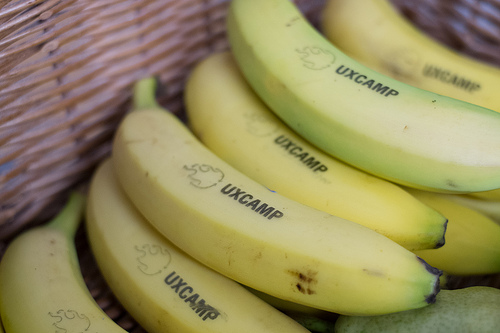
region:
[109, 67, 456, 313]
yellow banana with black lettering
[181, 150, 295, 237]
black lettering spelling uxcamp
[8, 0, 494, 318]
yellow bananas in brown basket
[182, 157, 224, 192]
black flame design on banana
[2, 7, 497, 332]
outdoor foreign market scene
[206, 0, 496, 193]
unripe slightly green banana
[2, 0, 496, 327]
brown wicker basket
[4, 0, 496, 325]
seven bananas visible in basket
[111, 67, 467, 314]
yellow banana with green stem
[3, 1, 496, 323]
yellow bananas with black stamps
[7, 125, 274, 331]
Three yellow bananas.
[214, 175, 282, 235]
Black letters that say uxcamp.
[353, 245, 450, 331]
Bottom of a banana peel.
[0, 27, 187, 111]
Brown woven side of a basket.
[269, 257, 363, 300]
Slight bruising of a banana skin.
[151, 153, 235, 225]
Flame symbol on a banana.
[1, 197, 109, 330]
Yellow banana in basket.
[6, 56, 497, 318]
Seven bananas in a basket.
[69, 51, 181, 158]
Top of a banana.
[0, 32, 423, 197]
Bananas in a basket.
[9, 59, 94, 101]
pink grooves in basket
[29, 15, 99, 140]
black lines in pink basket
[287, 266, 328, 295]
black spots on banana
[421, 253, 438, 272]
black tip on banana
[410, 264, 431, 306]
light green spot at end of banana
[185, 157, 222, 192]
small symbol on the banana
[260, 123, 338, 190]
bold black words on the banana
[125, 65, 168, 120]
green edge of banana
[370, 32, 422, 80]
small black bruising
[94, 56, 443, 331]
large bunches of yellow banana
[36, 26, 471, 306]
bananas inside container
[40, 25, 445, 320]
individual bananas laying side by side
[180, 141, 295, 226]
logo and name printed on bananas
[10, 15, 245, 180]
side of woven basket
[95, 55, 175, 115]
stem end of banana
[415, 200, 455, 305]
black marks at end of bananas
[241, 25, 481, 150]
greenish tint to banana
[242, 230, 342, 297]
blemish on banana peel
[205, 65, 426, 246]
yellowest banana of three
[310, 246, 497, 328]
different fruit under banana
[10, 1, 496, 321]
bananas lying side by side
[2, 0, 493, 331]
the bananas are almost ripe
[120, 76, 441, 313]
banana has a black stamp on it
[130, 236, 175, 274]
banana has a drawing stamped on it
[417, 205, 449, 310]
the tips of the bananas are black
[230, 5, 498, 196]
banana has green edges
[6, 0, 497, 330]
the bananas are in a basket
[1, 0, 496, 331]
the basket is a tight brown wicker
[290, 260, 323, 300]
the banana has brown spots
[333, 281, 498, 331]
a potato or stone is in the bottom of the basket